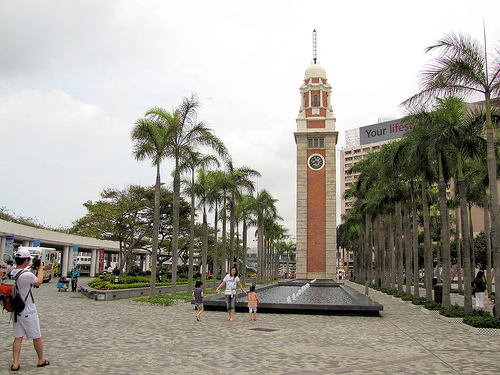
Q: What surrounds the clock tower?
A: Palm trees.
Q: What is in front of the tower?
A: A fountain.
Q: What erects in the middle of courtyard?
A: A clock tower.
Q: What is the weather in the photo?
A: Cloudy and overcast.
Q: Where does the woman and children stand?
A: In front of the fountain.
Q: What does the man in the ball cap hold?
A: A camera.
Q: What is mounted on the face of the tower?
A: A clock.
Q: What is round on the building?
A: Clock.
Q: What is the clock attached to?
A: Tower.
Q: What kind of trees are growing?
A: Palms.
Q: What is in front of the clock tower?
A: Fountain.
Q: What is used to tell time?
A: Clock.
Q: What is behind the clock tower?
A: Building.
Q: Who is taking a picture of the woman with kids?
A: A man.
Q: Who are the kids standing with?
A: A woman.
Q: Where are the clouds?
A: In the sky.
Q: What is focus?
A: Family in front of clock tower.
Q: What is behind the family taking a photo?
A: Fountain.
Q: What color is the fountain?
A: Black.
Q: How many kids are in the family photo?
A: 2.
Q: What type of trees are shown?
A: Palm trees.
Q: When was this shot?
A: Daytime.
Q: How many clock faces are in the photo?
A: 1.